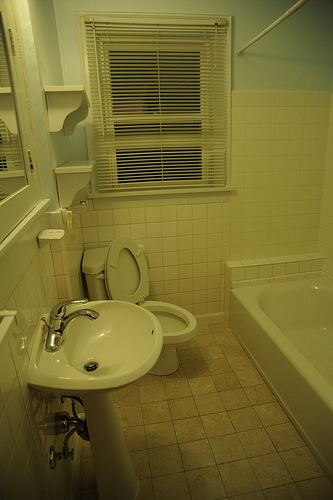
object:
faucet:
[41, 298, 100, 353]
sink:
[25, 298, 163, 393]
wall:
[232, 56, 331, 247]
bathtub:
[230, 275, 333, 484]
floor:
[144, 386, 269, 500]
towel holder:
[61, 199, 88, 223]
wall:
[10, 249, 55, 309]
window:
[76, 9, 234, 199]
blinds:
[83, 20, 228, 192]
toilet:
[104, 235, 199, 376]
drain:
[84, 361, 100, 372]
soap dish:
[37, 228, 66, 249]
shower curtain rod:
[237, 0, 307, 57]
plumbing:
[49, 400, 90, 470]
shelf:
[44, 85, 91, 136]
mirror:
[0, 33, 27, 201]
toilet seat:
[104, 234, 150, 305]